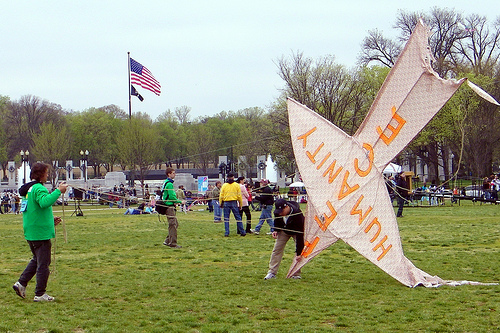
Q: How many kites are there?
A: One.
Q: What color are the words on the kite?
A: Orange.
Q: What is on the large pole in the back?
A: A flag.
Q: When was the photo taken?
A: Day time.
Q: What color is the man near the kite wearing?
A: Black.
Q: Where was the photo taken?
A: At a park.